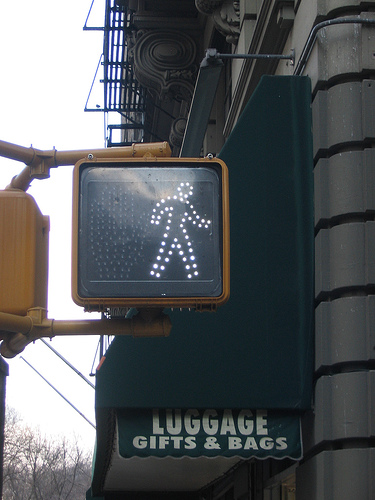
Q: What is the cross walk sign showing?
A: Walk.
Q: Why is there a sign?
A: To guide pedestrians.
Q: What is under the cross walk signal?
A: A sign.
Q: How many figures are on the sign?
A: One.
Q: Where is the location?
A: An intersection.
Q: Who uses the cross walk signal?
A: Pedestrians.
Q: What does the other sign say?
A: Luggage gifts & bags.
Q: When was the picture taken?
A: Daytime.